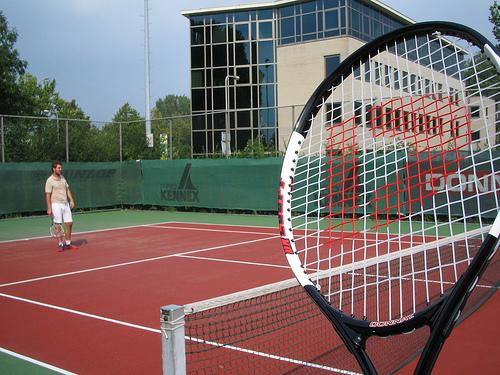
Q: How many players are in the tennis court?
A: One.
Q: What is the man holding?
A: A racket.